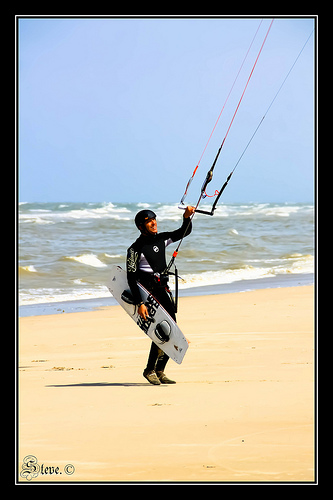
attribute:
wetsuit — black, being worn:
[121, 215, 194, 374]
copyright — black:
[19, 454, 76, 485]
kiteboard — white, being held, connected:
[102, 262, 190, 368]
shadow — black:
[42, 379, 165, 393]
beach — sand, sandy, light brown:
[18, 282, 315, 484]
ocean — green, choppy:
[15, 200, 315, 313]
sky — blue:
[19, 19, 315, 206]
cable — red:
[192, 17, 278, 209]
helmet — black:
[132, 207, 156, 228]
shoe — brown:
[141, 368, 161, 388]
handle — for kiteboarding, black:
[176, 205, 219, 219]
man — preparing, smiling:
[124, 204, 198, 389]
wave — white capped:
[255, 205, 304, 217]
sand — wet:
[19, 271, 317, 318]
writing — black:
[132, 293, 161, 336]